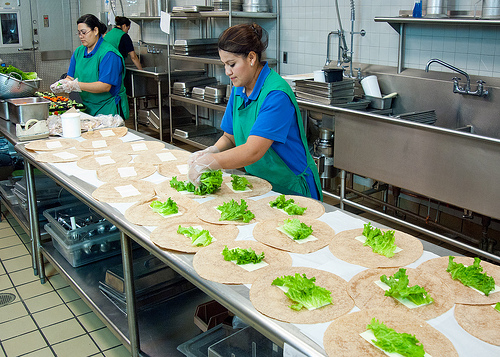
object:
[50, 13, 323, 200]
three women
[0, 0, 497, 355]
kitchen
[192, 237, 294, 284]
food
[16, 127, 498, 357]
tables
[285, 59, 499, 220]
sink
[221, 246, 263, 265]
lettuce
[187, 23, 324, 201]
worker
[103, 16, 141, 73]
woman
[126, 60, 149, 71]
plates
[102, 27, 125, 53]
green apron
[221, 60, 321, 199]
blue shirt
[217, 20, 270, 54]
hairnet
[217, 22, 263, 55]
hair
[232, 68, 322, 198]
apron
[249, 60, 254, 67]
earrings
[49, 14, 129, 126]
woman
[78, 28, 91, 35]
eyeglasses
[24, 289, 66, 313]
tiles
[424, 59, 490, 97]
faucet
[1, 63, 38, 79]
vegetables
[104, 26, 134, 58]
shirt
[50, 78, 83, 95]
gloves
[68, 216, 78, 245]
utensils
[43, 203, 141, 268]
bin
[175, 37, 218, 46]
pans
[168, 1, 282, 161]
rack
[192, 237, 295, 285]
tortilla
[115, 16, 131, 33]
head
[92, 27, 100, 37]
ear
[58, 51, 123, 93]
arm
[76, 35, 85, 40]
nose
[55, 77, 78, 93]
hand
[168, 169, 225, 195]
letuce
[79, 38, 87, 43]
mouth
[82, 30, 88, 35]
eye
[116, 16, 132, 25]
black hair